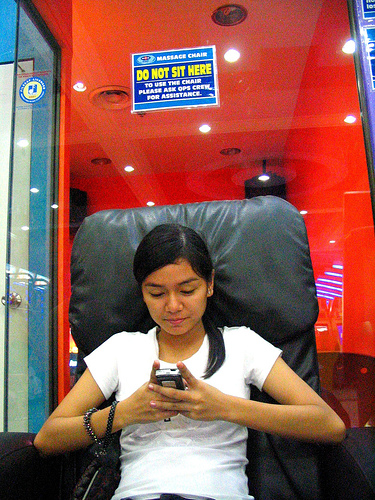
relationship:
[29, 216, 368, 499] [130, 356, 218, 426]
woman has hands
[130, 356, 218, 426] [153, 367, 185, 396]
hands holding cellphone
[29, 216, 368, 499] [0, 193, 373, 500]
woman sitting in chair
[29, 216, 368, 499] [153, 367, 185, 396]
woman looking at cellphone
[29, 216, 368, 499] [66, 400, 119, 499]
woman has handbag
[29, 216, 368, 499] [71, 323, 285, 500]
woman wearing shirt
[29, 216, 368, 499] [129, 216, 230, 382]
woman has hair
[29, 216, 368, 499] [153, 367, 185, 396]
woman holding cellphone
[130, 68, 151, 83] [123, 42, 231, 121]
do on sign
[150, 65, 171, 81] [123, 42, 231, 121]
not on sign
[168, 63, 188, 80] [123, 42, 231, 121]
sit on sign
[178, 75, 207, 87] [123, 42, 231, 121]
chair on sign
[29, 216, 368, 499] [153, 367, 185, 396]
woman with cellphone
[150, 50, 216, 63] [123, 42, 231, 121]
massage chair on sign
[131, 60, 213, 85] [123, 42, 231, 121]
do not sit here on sign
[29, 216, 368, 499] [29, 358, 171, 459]
woman has arm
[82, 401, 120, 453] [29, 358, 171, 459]
cord on arm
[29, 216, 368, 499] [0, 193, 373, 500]
woman in chair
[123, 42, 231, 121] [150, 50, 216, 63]
sign for massage chair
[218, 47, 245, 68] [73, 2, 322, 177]
can light on ceiling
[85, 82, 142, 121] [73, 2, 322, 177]
air vent in ceiling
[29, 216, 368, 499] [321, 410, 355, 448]
woman has elbow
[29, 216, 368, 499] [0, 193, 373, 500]
woman sits in chair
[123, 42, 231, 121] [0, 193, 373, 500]
sign above chair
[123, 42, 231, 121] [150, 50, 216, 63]
sign states massage chair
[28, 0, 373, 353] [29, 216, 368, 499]
walls behind woman